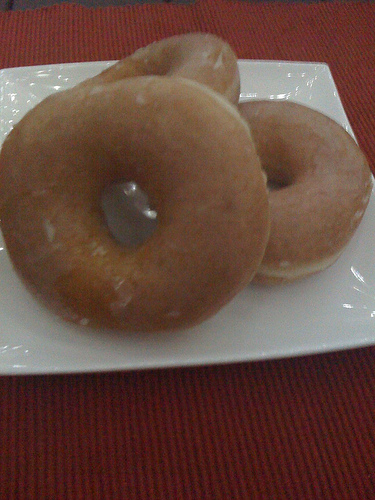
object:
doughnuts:
[0, 76, 269, 336]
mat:
[0, 0, 375, 500]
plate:
[0, 63, 375, 379]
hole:
[99, 177, 160, 244]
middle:
[45, 113, 216, 269]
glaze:
[0, 79, 269, 330]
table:
[0, 0, 374, 500]